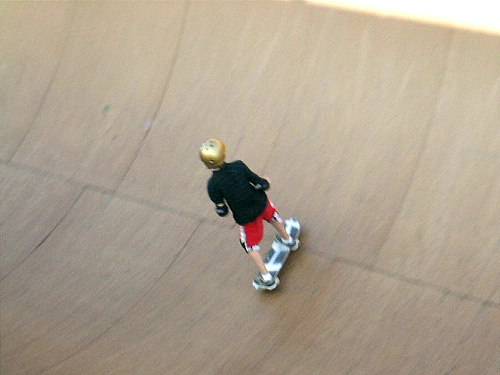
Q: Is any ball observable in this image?
A: No, there are no balls.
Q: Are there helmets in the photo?
A: Yes, there is a helmet.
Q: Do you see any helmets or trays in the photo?
A: Yes, there is a helmet.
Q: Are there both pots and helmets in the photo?
A: No, there is a helmet but no pots.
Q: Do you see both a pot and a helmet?
A: No, there is a helmet but no pots.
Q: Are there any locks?
A: No, there are no locks.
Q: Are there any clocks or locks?
A: No, there are no locks or clocks.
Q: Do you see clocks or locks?
A: No, there are no locks or clocks.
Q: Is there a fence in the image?
A: No, there are no fences.